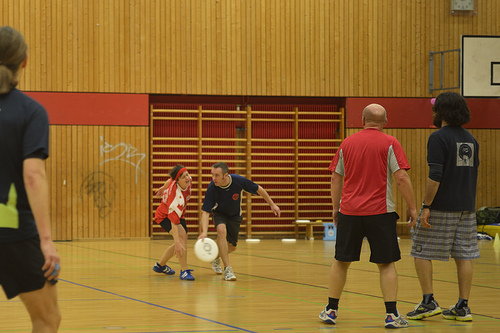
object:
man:
[195, 162, 280, 281]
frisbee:
[193, 236, 220, 263]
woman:
[149, 163, 195, 281]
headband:
[172, 166, 190, 180]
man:
[406, 91, 480, 321]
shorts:
[410, 209, 481, 261]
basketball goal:
[457, 35, 499, 97]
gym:
[1, 0, 499, 332]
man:
[317, 103, 419, 329]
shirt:
[328, 127, 410, 216]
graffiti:
[78, 136, 146, 218]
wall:
[0, 0, 500, 241]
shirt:
[198, 174, 257, 220]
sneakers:
[178, 269, 196, 281]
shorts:
[332, 206, 403, 264]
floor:
[1, 238, 500, 332]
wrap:
[53, 263, 58, 276]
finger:
[41, 260, 59, 284]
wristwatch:
[421, 202, 433, 211]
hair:
[429, 91, 471, 129]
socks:
[327, 297, 341, 312]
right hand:
[196, 229, 211, 245]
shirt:
[151, 183, 195, 225]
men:
[320, 91, 481, 328]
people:
[0, 25, 482, 332]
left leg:
[407, 252, 442, 320]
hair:
[171, 165, 187, 181]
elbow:
[25, 167, 43, 188]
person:
[0, 20, 62, 332]